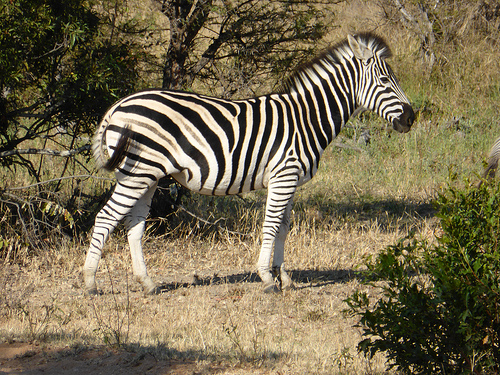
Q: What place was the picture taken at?
A: It was taken at the field.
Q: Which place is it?
A: It is a field.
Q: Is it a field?
A: Yes, it is a field.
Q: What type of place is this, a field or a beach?
A: It is a field.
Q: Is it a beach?
A: No, it is a field.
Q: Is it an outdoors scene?
A: Yes, it is outdoors.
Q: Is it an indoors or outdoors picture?
A: It is outdoors.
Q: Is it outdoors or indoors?
A: It is outdoors.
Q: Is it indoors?
A: No, it is outdoors.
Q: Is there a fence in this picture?
A: No, there are no fences.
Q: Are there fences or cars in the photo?
A: No, there are no fences or cars.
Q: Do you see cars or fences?
A: No, there are no fences or cars.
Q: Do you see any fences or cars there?
A: No, there are no fences or cars.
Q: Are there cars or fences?
A: No, there are no fences or cars.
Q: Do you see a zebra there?
A: Yes, there is a zebra.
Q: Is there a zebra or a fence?
A: Yes, there is a zebra.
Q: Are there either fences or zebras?
A: Yes, there is a zebra.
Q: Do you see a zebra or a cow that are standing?
A: Yes, the zebra is standing.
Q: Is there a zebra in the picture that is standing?
A: Yes, there is a zebra that is standing.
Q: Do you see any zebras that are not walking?
A: Yes, there is a zebra that is standing .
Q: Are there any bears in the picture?
A: No, there are no bears.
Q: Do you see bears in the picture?
A: No, there are no bears.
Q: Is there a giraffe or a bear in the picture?
A: No, there are no bears or giraffes.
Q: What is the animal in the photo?
A: The animal is a zebra.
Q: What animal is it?
A: The animal is a zebra.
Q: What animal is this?
A: This is a zebra.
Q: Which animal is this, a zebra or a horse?
A: This is a zebra.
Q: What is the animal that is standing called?
A: The animal is a zebra.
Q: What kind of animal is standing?
A: The animal is a zebra.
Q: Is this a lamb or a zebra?
A: This is a zebra.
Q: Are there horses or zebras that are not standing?
A: No, there is a zebra but it is standing.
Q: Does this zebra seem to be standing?
A: Yes, the zebra is standing.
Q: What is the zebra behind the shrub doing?
A: The zebra is standing.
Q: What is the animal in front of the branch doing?
A: The zebra is standing.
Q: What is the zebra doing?
A: The zebra is standing.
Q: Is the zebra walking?
A: No, the zebra is standing.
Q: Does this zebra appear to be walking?
A: No, the zebra is standing.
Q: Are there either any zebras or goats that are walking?
A: No, there is a zebra but it is standing.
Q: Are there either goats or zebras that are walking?
A: No, there is a zebra but it is standing.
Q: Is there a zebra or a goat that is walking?
A: No, there is a zebra but it is standing.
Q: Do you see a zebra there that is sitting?
A: No, there is a zebra but it is standing.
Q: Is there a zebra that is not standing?
A: No, there is a zebra but it is standing.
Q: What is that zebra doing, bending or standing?
A: The zebra is standing.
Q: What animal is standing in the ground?
A: The zebra is standing in the ground.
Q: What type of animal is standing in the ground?
A: The animal is a zebra.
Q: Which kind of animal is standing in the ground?
A: The animal is a zebra.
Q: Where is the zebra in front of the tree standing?
A: The zebra is standing in the ground.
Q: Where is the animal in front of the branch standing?
A: The zebra is standing in the ground.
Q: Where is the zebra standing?
A: The zebra is standing in the ground.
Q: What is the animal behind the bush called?
A: The animal is a zebra.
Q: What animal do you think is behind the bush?
A: The animal is a zebra.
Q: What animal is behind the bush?
A: The animal is a zebra.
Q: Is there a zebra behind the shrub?
A: Yes, there is a zebra behind the shrub.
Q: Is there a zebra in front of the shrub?
A: No, the zebra is behind the shrub.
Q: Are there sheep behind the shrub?
A: No, there is a zebra behind the shrub.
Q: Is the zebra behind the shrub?
A: Yes, the zebra is behind the shrub.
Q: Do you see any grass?
A: Yes, there is grass.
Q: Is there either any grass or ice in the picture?
A: Yes, there is grass.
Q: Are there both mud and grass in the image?
A: No, there is grass but no mud.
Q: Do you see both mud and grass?
A: No, there is grass but no mud.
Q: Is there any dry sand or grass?
A: Yes, there is dry grass.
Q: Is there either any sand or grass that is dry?
A: Yes, the grass is dry.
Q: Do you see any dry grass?
A: Yes, there is dry grass.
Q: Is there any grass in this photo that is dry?
A: Yes, there is grass that is dry.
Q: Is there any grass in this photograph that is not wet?
A: Yes, there is dry grass.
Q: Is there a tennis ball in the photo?
A: No, there are no tennis balls.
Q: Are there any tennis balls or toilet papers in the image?
A: No, there are no tennis balls or toilet papers.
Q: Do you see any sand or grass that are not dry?
A: No, there is grass but it is dry.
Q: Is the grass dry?
A: Yes, the grass is dry.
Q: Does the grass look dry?
A: Yes, the grass is dry.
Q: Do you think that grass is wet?
A: No, the grass is dry.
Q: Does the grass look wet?
A: No, the grass is dry.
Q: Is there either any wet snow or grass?
A: No, there is grass but it is dry.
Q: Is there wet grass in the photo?
A: No, there is grass but it is dry.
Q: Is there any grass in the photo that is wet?
A: No, there is grass but it is dry.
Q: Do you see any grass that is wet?
A: No, there is grass but it is dry.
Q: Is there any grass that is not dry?
A: No, there is grass but it is dry.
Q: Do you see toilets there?
A: No, there are no toilets.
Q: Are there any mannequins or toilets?
A: No, there are no toilets or mannequins.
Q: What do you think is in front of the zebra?
A: The bush is in front of the zebra.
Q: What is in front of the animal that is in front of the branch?
A: The bush is in front of the zebra.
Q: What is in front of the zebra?
A: The bush is in front of the zebra.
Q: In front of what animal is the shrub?
A: The shrub is in front of the zebra.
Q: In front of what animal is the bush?
A: The shrub is in front of the zebra.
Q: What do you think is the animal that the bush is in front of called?
A: The animal is a zebra.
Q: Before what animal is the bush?
A: The bush is in front of the zebra.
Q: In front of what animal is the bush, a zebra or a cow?
A: The bush is in front of a zebra.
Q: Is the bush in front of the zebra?
A: Yes, the bush is in front of the zebra.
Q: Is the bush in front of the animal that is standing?
A: Yes, the bush is in front of the zebra.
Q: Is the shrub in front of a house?
A: No, the shrub is in front of the zebra.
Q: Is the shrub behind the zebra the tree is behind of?
A: No, the shrub is in front of the zebra.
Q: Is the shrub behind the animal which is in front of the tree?
A: No, the shrub is in front of the zebra.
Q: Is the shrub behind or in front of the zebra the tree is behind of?
A: The shrub is in front of the zebra.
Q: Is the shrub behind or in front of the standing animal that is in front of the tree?
A: The shrub is in front of the zebra.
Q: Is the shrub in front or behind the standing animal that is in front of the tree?
A: The shrub is in front of the zebra.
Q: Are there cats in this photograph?
A: No, there are no cats.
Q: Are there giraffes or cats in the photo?
A: No, there are no cats or giraffes.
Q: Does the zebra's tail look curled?
A: Yes, the tail is curled.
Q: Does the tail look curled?
A: Yes, the tail is curled.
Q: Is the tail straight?
A: No, the tail is curled.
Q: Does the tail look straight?
A: No, the tail is curled.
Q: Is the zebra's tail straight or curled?
A: The tail is curled.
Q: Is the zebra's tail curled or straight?
A: The tail is curled.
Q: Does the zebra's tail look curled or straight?
A: The tail is curled.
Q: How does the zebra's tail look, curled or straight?
A: The tail is curled.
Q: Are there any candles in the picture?
A: No, there are no candles.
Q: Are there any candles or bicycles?
A: No, there are no candles or bicycles.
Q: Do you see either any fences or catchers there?
A: No, there are no fences or catchers.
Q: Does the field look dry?
A: Yes, the field is dry.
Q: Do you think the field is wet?
A: No, the field is dry.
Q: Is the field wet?
A: No, the field is dry.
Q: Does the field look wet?
A: No, the field is dry.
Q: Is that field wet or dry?
A: The field is dry.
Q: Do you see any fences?
A: No, there are no fences.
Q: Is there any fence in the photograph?
A: No, there are no fences.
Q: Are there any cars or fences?
A: No, there are no fences or cars.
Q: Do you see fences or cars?
A: No, there are no fences or cars.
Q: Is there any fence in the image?
A: No, there are no fences.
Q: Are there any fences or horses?
A: No, there are no fences or horses.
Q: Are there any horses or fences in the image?
A: No, there are no fences or horses.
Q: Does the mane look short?
A: Yes, the mane is short.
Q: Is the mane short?
A: Yes, the mane is short.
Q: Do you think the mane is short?
A: Yes, the mane is short.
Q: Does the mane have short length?
A: Yes, the mane is short.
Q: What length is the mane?
A: The mane is short.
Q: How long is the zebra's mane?
A: The mane is short.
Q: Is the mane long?
A: No, the mane is short.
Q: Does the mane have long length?
A: No, the mane is short.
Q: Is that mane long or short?
A: The mane is short.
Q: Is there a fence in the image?
A: No, there are no fences.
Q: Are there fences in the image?
A: No, there are no fences.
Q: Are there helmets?
A: No, there are no helmets.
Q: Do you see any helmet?
A: No, there are no helmets.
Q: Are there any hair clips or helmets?
A: No, there are no helmets or hair clips.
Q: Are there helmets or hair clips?
A: No, there are no helmets or hair clips.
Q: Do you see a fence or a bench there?
A: No, there are no fences or benches.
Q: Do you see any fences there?
A: No, there are no fences.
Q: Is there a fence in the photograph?
A: No, there are no fences.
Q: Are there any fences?
A: No, there are no fences.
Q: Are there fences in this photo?
A: No, there are no fences.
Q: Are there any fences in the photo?
A: No, there are no fences.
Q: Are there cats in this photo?
A: No, there are no cats.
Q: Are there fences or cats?
A: No, there are no cats or fences.